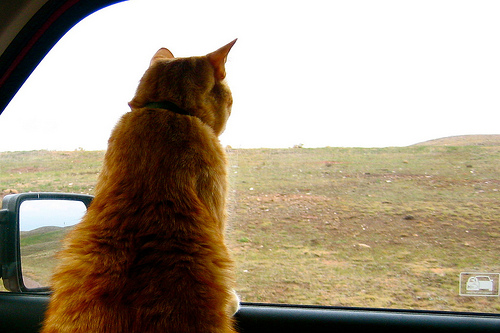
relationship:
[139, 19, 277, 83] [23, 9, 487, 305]
ears outside window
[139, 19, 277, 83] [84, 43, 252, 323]
ears of cats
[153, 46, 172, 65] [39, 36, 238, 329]
ear of cat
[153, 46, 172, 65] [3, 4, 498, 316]
ear outside window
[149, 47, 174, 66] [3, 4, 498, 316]
ear outside window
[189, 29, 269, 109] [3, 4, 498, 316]
ear outside window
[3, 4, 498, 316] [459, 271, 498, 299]
window has a sticker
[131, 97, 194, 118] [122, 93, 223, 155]
collar on neck